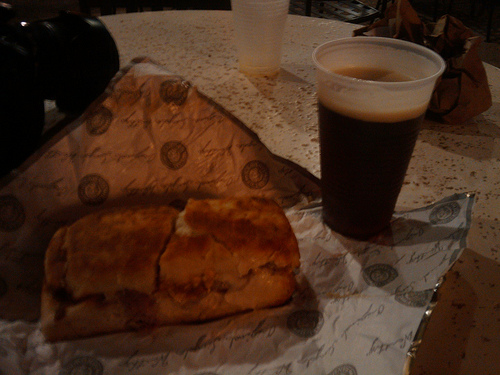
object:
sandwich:
[37, 201, 304, 342]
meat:
[64, 260, 276, 316]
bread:
[31, 192, 300, 342]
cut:
[148, 198, 201, 322]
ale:
[314, 94, 425, 241]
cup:
[310, 34, 446, 242]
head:
[313, 62, 446, 127]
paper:
[4, 57, 477, 375]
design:
[54, 81, 254, 197]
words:
[364, 326, 413, 359]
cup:
[232, 0, 288, 73]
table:
[2, 7, 499, 374]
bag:
[352, 1, 500, 121]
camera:
[0, 6, 120, 153]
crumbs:
[243, 76, 314, 171]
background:
[0, 2, 500, 96]